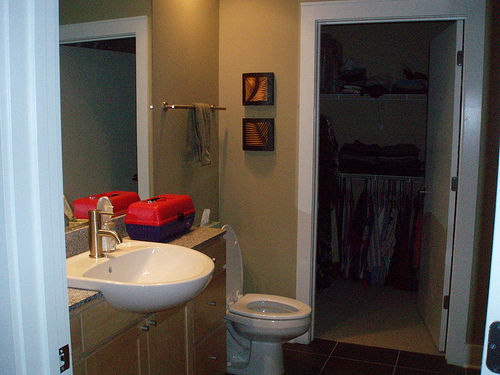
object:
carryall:
[122, 192, 196, 244]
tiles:
[281, 336, 338, 356]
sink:
[58, 238, 216, 314]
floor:
[280, 338, 482, 374]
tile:
[328, 341, 398, 368]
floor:
[311, 285, 445, 356]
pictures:
[239, 72, 274, 105]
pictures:
[240, 117, 272, 149]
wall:
[216, 1, 298, 340]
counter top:
[65, 225, 227, 308]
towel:
[182, 102, 214, 169]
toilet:
[219, 222, 312, 374]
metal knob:
[140, 323, 150, 332]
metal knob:
[146, 318, 158, 327]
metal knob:
[205, 301, 219, 309]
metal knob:
[209, 355, 219, 361]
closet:
[310, 16, 466, 356]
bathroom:
[0, 0, 499, 374]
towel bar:
[160, 103, 228, 111]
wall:
[58, 0, 219, 234]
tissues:
[198, 207, 213, 228]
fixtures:
[86, 208, 122, 259]